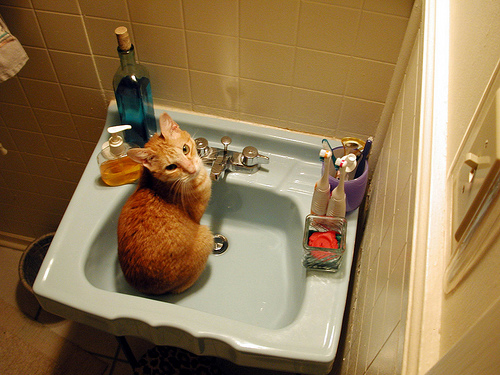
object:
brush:
[317, 139, 341, 171]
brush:
[311, 148, 333, 217]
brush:
[323, 156, 346, 218]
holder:
[325, 157, 348, 219]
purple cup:
[317, 144, 370, 214]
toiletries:
[320, 134, 378, 180]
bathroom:
[0, 0, 499, 375]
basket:
[18, 230, 54, 295]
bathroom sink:
[26, 91, 360, 373]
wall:
[340, 0, 497, 375]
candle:
[304, 217, 352, 276]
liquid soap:
[95, 123, 142, 184]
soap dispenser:
[97, 119, 133, 165]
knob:
[194, 137, 209, 158]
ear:
[126, 142, 151, 171]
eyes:
[182, 143, 192, 157]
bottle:
[107, 25, 162, 148]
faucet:
[186, 135, 269, 182]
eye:
[163, 162, 178, 177]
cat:
[116, 110, 213, 296]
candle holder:
[301, 210, 348, 277]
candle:
[307, 229, 339, 262]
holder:
[299, 212, 344, 273]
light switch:
[451, 60, 500, 243]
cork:
[115, 21, 131, 51]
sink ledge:
[32, 95, 362, 373]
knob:
[240, 145, 270, 172]